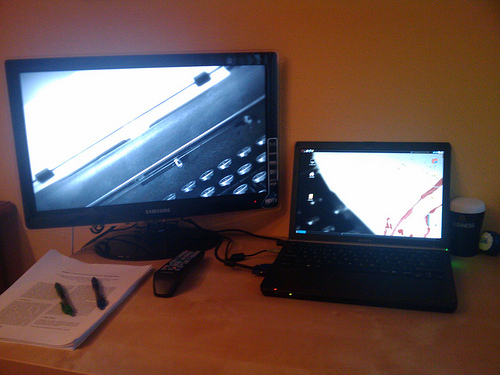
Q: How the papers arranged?
A: Stack.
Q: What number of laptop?
A: One.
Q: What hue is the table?
A: Brown.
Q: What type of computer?
A: Laptop.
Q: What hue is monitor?
A: Black.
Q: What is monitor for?
A: Computer.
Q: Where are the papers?
A: On desk.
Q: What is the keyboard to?
A: Laptop.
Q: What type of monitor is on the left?
A: A Samsung.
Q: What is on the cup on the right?
A: Guinness.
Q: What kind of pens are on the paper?
A: Blue and green.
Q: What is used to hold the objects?
A: Office desk.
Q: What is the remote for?
A: To turn off the monitor.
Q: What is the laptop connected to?
A: The monitor.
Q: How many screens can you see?
A: Two.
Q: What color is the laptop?
A: Black.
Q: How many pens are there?
A: Two.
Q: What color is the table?
A: Brown.